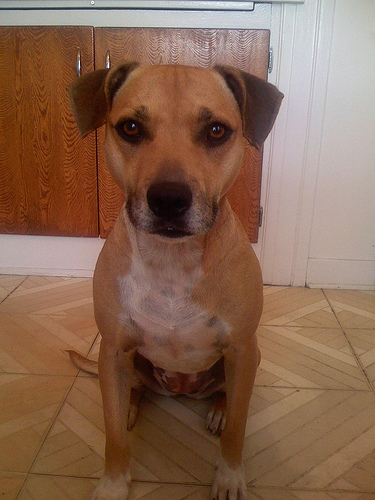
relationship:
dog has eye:
[55, 57, 258, 493] [101, 101, 162, 156]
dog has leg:
[55, 57, 258, 493] [216, 323, 270, 498]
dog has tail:
[55, 57, 258, 493] [75, 340, 114, 388]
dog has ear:
[55, 57, 258, 493] [215, 61, 291, 151]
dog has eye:
[55, 57, 258, 493] [196, 112, 246, 153]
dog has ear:
[55, 57, 258, 493] [63, 34, 179, 144]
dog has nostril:
[55, 57, 258, 493] [143, 194, 166, 219]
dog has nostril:
[55, 57, 258, 493] [172, 192, 203, 226]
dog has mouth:
[55, 57, 258, 493] [134, 223, 203, 253]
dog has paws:
[55, 57, 258, 493] [85, 446, 268, 498]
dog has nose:
[55, 57, 258, 493] [136, 152, 195, 214]